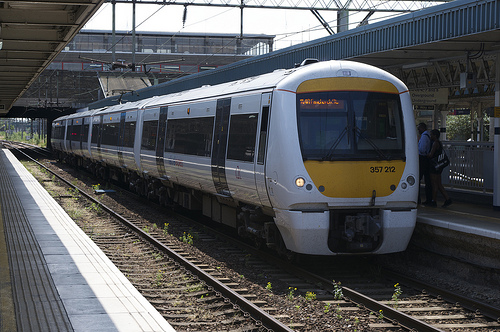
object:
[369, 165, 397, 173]
black numbers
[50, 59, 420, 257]
train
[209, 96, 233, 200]
doors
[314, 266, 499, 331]
tracks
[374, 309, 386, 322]
plant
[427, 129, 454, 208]
person c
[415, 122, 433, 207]
man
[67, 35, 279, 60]
overpass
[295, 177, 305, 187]
light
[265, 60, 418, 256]
front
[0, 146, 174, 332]
platform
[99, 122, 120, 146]
windows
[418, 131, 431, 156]
shirt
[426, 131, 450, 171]
bag